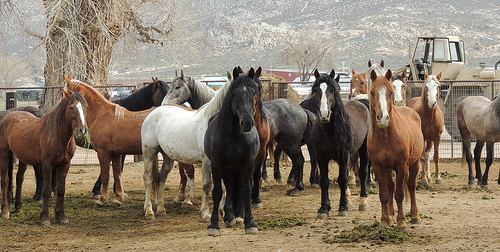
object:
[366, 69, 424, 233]
horse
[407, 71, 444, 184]
horse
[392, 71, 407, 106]
horse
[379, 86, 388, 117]
striped nose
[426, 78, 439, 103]
striped nose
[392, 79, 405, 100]
striped nose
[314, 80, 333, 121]
faces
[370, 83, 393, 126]
face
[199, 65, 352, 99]
buildings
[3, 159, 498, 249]
ground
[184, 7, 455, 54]
hill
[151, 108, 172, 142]
back part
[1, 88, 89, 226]
brown horse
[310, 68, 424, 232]
two horses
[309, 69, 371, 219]
horse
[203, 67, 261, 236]
black horse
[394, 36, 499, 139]
machinery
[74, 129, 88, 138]
mouth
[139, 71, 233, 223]
horse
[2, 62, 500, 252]
corral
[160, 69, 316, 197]
horse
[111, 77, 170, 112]
horse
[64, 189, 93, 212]
hay